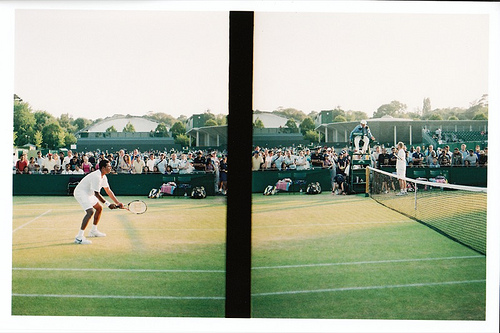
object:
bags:
[262, 185, 279, 196]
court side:
[15, 156, 385, 197]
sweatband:
[103, 201, 111, 207]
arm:
[92, 175, 110, 207]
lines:
[12, 292, 225, 301]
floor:
[27, 237, 497, 316]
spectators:
[72, 164, 84, 175]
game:
[13, 159, 429, 297]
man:
[72, 159, 124, 245]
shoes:
[74, 238, 92, 245]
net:
[367, 165, 488, 257]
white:
[72, 169, 110, 210]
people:
[168, 153, 180, 173]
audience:
[19, 138, 480, 191]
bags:
[172, 183, 193, 197]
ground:
[22, 190, 471, 311]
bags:
[305, 180, 323, 195]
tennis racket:
[109, 200, 147, 215]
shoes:
[88, 230, 105, 236]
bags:
[147, 188, 166, 199]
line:
[13, 256, 477, 274]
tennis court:
[24, 192, 483, 322]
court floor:
[24, 190, 480, 322]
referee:
[349, 120, 375, 154]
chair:
[352, 136, 370, 155]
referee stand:
[344, 137, 374, 195]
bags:
[160, 181, 177, 195]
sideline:
[19, 168, 484, 194]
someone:
[394, 141, 409, 196]